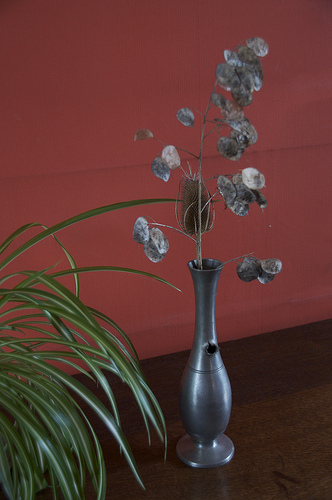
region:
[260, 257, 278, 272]
metallic leaf of plant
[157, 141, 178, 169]
metallic leaf of plant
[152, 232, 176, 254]
metallic leaf of plant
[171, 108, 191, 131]
metallic leaf of plant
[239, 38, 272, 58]
metallic leaf of plant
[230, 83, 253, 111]
metallic leaf of plant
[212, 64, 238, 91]
metallic leaf of plant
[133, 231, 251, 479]
silver base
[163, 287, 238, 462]
silver base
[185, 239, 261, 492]
silver vase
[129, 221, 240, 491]
silver vase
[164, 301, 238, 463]
silver vase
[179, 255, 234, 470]
a silver vase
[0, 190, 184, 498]
long green leaves leaves on a plant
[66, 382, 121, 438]
a white stripe on a leaf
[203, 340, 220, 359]
a hole in a vase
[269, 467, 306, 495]
marks on a table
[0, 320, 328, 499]
a brown wood table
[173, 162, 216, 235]
a brown cone shaped flower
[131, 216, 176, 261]
round silver leaves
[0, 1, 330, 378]
a pink painted wall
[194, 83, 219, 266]
a stem of a plant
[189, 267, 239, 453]
The vase is silver.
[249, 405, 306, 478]
Vase is on a table.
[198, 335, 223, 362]
Hole in the vase.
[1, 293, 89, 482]
The leaves are green.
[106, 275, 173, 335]
The wall is red.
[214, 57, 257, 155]
The flowers are grey.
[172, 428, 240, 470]
The base is round.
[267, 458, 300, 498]
Dark brown on the table.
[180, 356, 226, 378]
Line on the vase.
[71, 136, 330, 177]
Line in the wall.